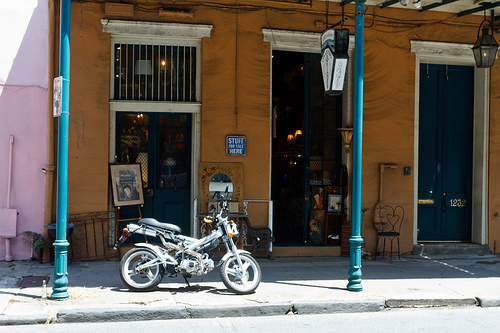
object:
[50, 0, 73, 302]
post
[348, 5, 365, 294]
post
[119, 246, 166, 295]
wheel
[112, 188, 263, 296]
motorcyle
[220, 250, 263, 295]
wheel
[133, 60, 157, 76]
lampsade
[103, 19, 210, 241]
windwo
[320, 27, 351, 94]
sign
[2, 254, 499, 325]
sidewalk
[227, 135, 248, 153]
sign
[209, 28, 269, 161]
wall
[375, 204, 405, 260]
chair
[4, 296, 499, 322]
curb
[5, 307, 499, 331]
road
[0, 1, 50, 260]
facade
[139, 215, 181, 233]
seat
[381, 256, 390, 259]
stopper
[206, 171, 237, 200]
mirror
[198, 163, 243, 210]
frame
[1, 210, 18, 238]
fusebox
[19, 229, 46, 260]
plant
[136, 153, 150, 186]
lampsade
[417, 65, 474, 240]
door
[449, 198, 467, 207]
number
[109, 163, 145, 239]
easel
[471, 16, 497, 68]
lamp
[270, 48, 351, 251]
doorway